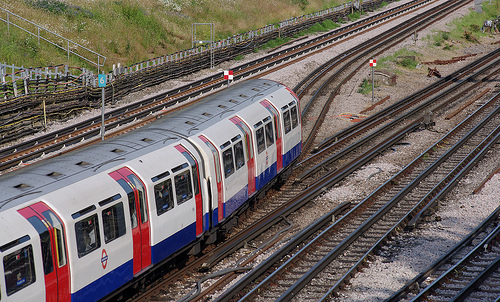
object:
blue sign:
[98, 74, 106, 87]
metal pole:
[100, 87, 106, 141]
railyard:
[2, 1, 498, 302]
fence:
[0, 7, 107, 81]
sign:
[369, 59, 376, 67]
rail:
[1, 9, 106, 79]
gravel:
[0, 0, 469, 302]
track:
[241, 48, 500, 302]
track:
[0, 0, 470, 302]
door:
[197, 134, 224, 222]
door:
[172, 143, 204, 235]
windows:
[75, 194, 124, 258]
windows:
[74, 199, 125, 258]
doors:
[258, 99, 283, 173]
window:
[221, 140, 246, 177]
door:
[106, 166, 150, 275]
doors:
[18, 200, 73, 302]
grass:
[20, 0, 107, 29]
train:
[0, 78, 301, 302]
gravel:
[100, 50, 500, 302]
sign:
[224, 70, 233, 79]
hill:
[0, 0, 356, 77]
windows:
[6, 244, 33, 297]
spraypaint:
[336, 112, 372, 122]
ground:
[335, 96, 363, 119]